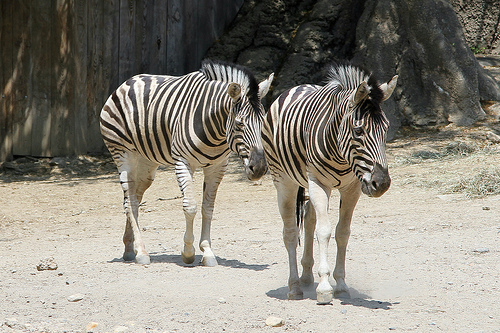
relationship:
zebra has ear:
[265, 51, 398, 306] [345, 83, 371, 111]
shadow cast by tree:
[28, 124, 152, 172] [29, 6, 474, 111]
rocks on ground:
[35, 249, 72, 299] [16, 176, 116, 326]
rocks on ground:
[35, 249, 72, 299] [20, 168, 476, 318]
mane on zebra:
[326, 65, 383, 116] [265, 51, 398, 306]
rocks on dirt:
[35, 249, 72, 299] [26, 166, 460, 319]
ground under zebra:
[16, 177, 473, 312] [265, 51, 398, 306]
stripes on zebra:
[134, 78, 224, 163] [265, 51, 398, 306]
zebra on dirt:
[265, 51, 398, 306] [15, 183, 471, 315]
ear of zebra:
[352, 70, 419, 114] [265, 51, 398, 306]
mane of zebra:
[331, 65, 405, 106] [265, 51, 398, 306]